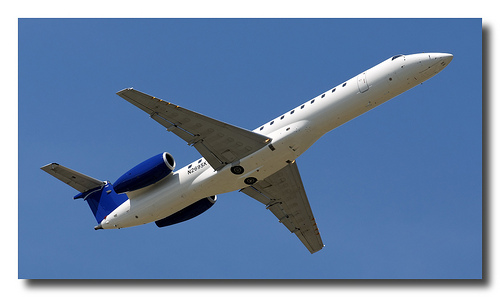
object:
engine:
[152, 192, 216, 228]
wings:
[109, 81, 275, 172]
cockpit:
[385, 52, 410, 66]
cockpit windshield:
[387, 51, 408, 61]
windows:
[333, 77, 350, 88]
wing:
[37, 161, 104, 193]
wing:
[231, 147, 330, 256]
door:
[352, 70, 374, 97]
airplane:
[36, 50, 456, 254]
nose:
[400, 49, 455, 82]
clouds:
[336, 132, 461, 249]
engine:
[105, 149, 181, 196]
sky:
[19, 17, 484, 279]